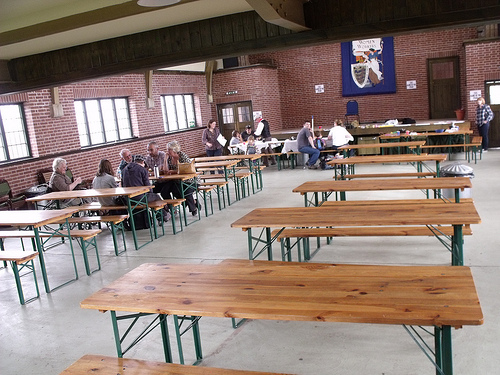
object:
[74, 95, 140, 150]
window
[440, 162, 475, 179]
can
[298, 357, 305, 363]
spot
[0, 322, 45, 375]
floor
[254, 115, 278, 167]
person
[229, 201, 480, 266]
table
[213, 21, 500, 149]
wall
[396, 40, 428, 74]
bricks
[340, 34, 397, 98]
decorations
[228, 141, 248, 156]
tablecloth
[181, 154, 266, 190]
table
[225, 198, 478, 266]
table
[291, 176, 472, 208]
table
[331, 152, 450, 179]
table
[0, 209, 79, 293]
table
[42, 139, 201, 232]
group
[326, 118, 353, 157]
person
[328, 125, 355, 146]
white shirt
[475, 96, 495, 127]
shirt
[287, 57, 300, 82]
bricks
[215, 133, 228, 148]
paper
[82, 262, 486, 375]
table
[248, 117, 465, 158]
stage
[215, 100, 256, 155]
doors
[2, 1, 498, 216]
building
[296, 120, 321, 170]
people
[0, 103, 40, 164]
window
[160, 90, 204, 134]
window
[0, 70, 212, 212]
wall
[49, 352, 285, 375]
wood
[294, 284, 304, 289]
spot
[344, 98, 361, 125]
chair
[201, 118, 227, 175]
person